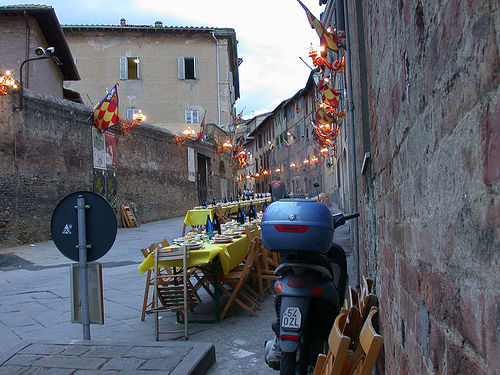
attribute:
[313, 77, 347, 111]
flag — multicolored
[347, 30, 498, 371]
brick wall — old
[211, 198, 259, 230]
bottles — blue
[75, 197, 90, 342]
post — metal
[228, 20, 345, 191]
lights — colored, orange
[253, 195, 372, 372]
motorcycle — gray, colored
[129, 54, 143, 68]
light — illuminated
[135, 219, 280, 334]
chairs — brown, wooden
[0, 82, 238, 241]
wall — stone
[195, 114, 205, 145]
flag — multicolored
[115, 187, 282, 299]
table cloth — yellow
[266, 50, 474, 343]
wall — stone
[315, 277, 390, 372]
chairs — folded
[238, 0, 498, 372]
wall — stone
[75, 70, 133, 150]
flag — multi colored